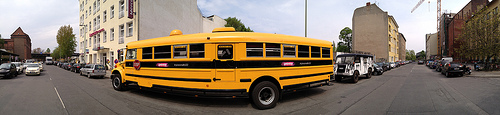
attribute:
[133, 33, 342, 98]
school bus — yellow, long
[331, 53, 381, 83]
jeep — parked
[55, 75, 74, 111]
stripe — large, white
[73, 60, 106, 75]
van — parked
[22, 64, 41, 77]
car — driving, white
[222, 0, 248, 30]
tree — green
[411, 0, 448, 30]
crane — tall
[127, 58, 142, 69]
stop sign — red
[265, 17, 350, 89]
bus — yellow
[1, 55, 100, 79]
cars — parked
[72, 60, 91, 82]
minivan — gray